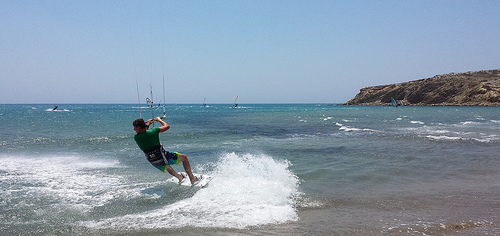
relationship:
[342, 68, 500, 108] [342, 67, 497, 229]
grass hill in corner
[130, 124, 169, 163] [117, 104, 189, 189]
shirt on surfer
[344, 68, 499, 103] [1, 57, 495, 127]
point in background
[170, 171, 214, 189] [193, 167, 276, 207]
board on water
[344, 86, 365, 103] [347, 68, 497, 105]
edge of rock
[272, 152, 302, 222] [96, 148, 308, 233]
edge of wave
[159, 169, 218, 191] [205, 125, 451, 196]
board on water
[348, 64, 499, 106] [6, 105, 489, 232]
cliff near water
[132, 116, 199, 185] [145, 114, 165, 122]
man has bar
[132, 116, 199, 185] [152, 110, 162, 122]
man has hand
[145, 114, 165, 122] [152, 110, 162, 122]
bar in hand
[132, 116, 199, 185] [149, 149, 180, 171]
man wears shorts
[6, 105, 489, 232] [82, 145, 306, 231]
water has some wave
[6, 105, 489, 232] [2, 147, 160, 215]
water has some wave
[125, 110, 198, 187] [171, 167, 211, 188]
man on board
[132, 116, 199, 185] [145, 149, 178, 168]
man wearing swim trunks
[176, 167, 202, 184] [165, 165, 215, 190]
feet on board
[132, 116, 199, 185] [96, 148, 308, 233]
man creating a wave